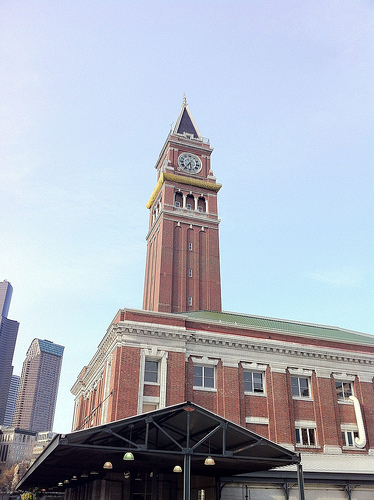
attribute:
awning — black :
[21, 409, 324, 490]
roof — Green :
[228, 314, 308, 341]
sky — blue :
[5, 5, 372, 115]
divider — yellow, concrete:
[155, 178, 203, 190]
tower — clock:
[153, 93, 302, 250]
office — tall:
[11, 337, 63, 433]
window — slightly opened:
[243, 371, 263, 391]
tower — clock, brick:
[137, 79, 233, 329]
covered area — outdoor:
[11, 394, 311, 498]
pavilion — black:
[134, 412, 237, 498]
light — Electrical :
[111, 442, 130, 459]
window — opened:
[291, 424, 319, 449]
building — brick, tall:
[69, 89, 373, 498]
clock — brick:
[156, 146, 216, 195]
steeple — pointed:
[170, 93, 203, 138]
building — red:
[69, 306, 372, 498]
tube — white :
[346, 385, 367, 458]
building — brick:
[63, 78, 341, 449]